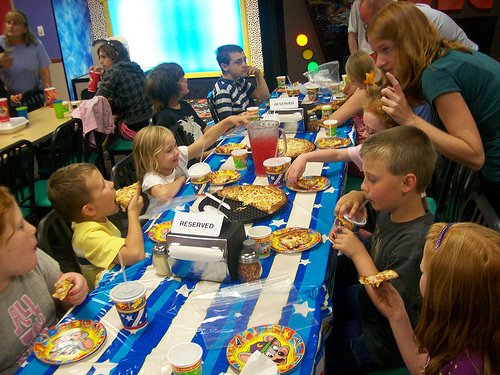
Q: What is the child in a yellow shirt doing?
A: Eating pizza.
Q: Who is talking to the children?
A: An adult.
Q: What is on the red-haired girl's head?
A: Purple headband.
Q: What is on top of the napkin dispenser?
A: Reserved sign.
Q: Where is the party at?
A: Chucky Cheese.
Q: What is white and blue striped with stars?
A: Tablecloth.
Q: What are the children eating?
A: Pizza.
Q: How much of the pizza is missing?
A: Half.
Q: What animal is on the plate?
A: Mouse.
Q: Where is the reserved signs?
A: Napkin dispensers.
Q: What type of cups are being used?
A: Paper.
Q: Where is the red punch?
A: Pitcher.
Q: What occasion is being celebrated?
A: Birthday.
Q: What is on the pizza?
A: Cheese.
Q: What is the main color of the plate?
A: Yellow.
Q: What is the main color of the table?
A: Blue.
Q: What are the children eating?
A: Pizza.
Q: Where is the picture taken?
A: A party.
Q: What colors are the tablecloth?
A: Blue and white.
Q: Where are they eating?
A: At the table.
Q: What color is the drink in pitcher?
A: Red.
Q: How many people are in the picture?
A: Thirteen.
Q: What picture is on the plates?
A: Chuck E Cheese.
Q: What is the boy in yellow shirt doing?
A: Eating.